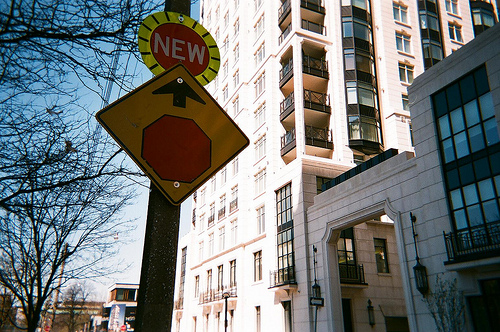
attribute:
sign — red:
[139, 6, 226, 88]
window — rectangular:
[444, 110, 466, 132]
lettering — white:
[151, 30, 207, 66]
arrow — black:
[150, 76, 208, 110]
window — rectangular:
[463, 108, 480, 145]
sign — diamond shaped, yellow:
[96, 60, 253, 202]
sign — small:
[97, 5, 274, 215]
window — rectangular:
[394, 92, 456, 164]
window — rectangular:
[442, 94, 464, 143]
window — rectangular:
[429, 109, 459, 140]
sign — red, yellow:
[133, 103, 223, 193]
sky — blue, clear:
[0, 4, 176, 249]